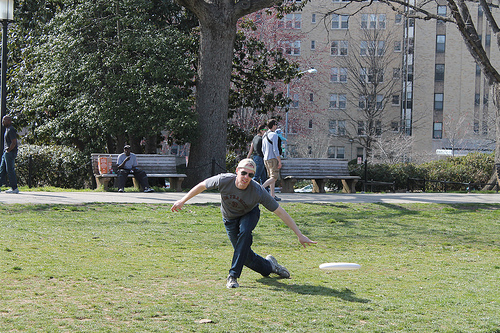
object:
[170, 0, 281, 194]
tree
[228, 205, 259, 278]
leg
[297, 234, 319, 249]
hand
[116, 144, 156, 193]
man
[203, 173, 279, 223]
shirt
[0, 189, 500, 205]
road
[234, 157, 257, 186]
head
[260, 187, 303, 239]
arm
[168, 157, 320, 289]
person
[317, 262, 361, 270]
frisbee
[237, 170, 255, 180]
sunglasses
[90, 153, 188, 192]
bench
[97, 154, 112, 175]
bag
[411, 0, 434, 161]
wall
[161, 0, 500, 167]
building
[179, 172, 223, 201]
arm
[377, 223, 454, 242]
air